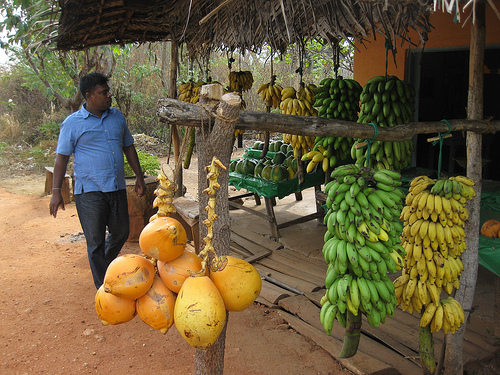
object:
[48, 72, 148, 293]
man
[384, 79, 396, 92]
food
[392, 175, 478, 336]
stack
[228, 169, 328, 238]
table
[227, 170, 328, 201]
tarp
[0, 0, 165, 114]
tree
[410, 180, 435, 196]
bananas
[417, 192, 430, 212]
bananas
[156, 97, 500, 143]
trunk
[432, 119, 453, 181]
hook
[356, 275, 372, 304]
bananas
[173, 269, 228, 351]
coconut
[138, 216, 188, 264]
fruit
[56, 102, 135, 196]
shirt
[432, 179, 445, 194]
bananas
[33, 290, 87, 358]
dirt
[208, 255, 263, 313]
fruit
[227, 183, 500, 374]
floor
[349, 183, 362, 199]
banana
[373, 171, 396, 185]
bananas